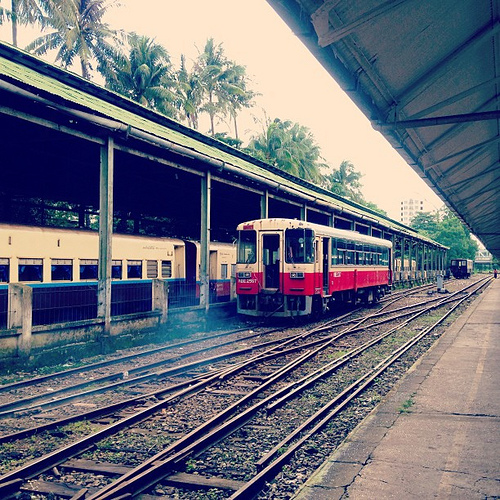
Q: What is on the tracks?
A: Red and white train.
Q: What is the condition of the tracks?
A: Old and grassy.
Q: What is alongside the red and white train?
A: A train.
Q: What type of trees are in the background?
A: Palm.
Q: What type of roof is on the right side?
A: Metal.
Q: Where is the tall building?
A: Behind the train station.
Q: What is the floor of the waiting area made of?
A: Cement.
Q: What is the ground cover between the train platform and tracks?
A: Gravel.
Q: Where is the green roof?
A: Left side over the white train.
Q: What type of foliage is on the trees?
A: Palm fronds.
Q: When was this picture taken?
A: During the day.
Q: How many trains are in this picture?
A: Three.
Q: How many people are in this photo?
A: Zero.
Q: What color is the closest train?
A: White and red.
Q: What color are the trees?
A: Green.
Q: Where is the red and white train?
A: On the tracks.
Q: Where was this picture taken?
A: A train station.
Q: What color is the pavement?
A: Brown.